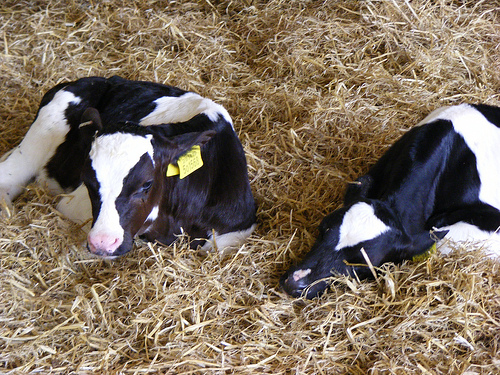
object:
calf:
[0, 74, 256, 260]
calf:
[282, 102, 500, 300]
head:
[61, 98, 221, 257]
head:
[278, 170, 448, 297]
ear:
[160, 121, 215, 177]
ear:
[387, 227, 447, 258]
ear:
[336, 173, 378, 207]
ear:
[65, 111, 103, 149]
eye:
[132, 181, 154, 193]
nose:
[279, 261, 321, 294]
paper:
[165, 142, 204, 179]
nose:
[279, 265, 309, 297]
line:
[85, 130, 155, 245]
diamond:
[335, 204, 392, 250]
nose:
[86, 231, 121, 252]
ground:
[0, 0, 500, 375]